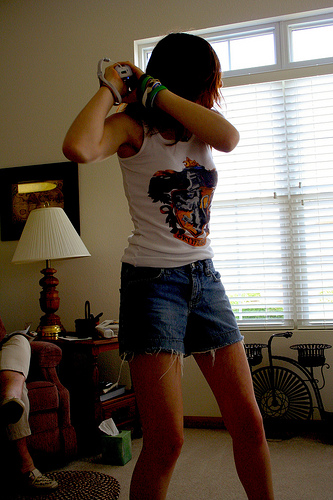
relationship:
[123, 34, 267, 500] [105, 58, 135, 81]
girl holding remote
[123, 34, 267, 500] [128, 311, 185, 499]
girl has leg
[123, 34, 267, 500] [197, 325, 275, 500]
girl has leg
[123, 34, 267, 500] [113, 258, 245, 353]
girl wearing shorts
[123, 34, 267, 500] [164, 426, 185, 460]
girl has knee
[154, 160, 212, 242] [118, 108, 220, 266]
design printed on shirt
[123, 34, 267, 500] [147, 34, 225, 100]
girl has hair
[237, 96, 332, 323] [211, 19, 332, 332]
blinds hanging on window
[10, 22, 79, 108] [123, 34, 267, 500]
wall next to girl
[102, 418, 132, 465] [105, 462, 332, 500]
tissue box on top of floor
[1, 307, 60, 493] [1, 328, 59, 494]
woman has legs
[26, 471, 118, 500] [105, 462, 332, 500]
rug on top of floor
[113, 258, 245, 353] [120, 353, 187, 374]
shorts have strings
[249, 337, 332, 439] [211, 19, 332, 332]
decoration under window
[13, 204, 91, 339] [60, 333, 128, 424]
lamp on top of table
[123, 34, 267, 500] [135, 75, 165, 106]
girl wearing bracelets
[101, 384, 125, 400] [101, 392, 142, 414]
book sitting on shelf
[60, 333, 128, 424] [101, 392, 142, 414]
table has shelf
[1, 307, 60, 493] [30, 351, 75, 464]
woman sitting on sofa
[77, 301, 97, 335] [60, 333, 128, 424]
basket on top of table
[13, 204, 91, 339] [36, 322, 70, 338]
lamp has brass base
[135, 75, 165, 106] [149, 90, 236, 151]
bracelets wrapped around arm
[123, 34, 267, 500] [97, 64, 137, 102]
girl playing video game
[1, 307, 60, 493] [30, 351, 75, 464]
woman sitting on top of sofa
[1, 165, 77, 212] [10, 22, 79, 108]
poster hanging on wall